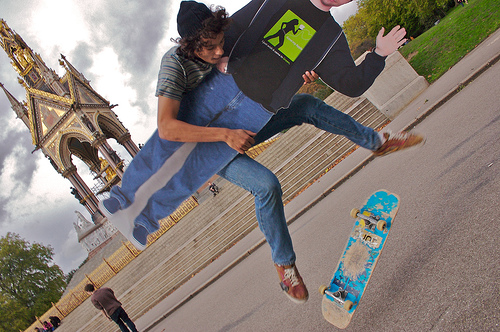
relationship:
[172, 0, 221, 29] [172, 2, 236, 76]
cap on head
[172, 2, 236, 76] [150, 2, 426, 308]
head of skateboarder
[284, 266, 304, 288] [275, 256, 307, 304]
lace on shoe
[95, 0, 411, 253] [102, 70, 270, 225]
cut out wearing jeans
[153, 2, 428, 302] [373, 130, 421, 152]
man wearing shoes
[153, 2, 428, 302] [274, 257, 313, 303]
man wearing shoes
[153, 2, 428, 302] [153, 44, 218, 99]
man wearing shirt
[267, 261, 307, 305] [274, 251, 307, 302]
shoe on foot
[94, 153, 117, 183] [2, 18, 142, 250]
statue in monument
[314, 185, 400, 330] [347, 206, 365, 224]
skateboard has wheel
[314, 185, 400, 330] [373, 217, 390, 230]
skateboard has wheel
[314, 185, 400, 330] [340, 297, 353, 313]
skateboard has wheel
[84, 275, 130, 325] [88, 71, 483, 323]
man standing on pavement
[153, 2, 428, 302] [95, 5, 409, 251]
man holding a sign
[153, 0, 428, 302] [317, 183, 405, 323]
man has  a skateboard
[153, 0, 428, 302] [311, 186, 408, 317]
man has  a skateboard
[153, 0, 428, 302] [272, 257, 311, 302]
man wearing shoe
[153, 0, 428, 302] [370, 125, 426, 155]
man wearing shoe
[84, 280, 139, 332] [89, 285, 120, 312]
man wearing a shirt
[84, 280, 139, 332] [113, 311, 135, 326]
man wearing pants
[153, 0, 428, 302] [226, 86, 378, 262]
man wearing jeans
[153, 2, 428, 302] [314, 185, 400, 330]
man above skateboard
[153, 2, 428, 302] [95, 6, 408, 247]
man holding cut out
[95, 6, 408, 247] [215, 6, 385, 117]
cut out has shirt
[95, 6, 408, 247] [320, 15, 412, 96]
cut out has arm up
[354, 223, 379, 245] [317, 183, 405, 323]
trim on skateboard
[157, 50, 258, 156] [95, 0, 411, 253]
arm holding cut out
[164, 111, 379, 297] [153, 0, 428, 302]
jeans on man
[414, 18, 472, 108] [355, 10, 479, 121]
leaf on plant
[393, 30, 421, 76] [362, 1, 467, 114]
leaf on plant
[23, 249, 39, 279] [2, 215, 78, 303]
leaf on plant